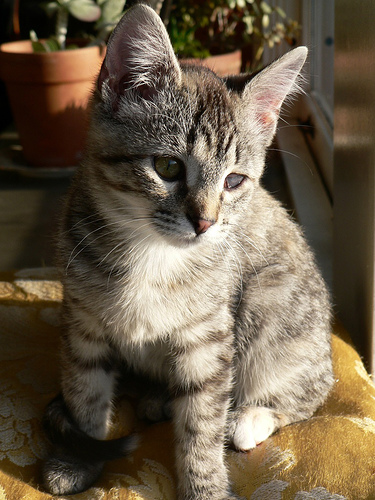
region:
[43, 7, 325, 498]
a kitten sitting on a table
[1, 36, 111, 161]
a clay pot sitting on the table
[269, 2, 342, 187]
the window next to the plants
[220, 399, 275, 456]
the white paw of the kitty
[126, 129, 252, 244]
the sad looking kitty face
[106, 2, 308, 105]
the big ears of the kitty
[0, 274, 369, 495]
the blanket the kitty is sitting on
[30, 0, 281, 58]
the plants sitting in the pots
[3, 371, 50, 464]
the flower on the blanket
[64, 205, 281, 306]
the whiskers on the kitty's face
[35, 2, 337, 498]
the kitten on the cushion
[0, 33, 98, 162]
the potted plant behind the kitten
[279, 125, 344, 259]
the window sill behind the kitten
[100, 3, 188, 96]
the ear of the kitten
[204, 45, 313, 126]
the ear of the kitten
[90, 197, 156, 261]
the whiskers on the kitten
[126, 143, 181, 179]
the eye of the kitten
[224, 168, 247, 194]
the eye of the kitten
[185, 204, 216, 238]
the nose of the kitten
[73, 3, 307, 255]
the head of the kitten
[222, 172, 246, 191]
Cat's left eye is milky colored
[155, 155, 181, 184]
Cat has dark right eye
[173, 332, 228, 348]
Cat's fur has grey stripes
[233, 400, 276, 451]
Cat's back paw is white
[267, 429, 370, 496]
soft yellow seating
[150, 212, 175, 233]
Cat's mouth has black dots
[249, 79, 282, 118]
Cat's left ear is pink inside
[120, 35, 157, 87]
Cat has fur in ears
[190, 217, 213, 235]
pink and black nose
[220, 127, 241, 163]
a triangle on cat's head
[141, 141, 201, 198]
a green eye on face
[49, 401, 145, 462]
a tail curled around a leg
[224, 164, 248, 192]
an eye socket on cat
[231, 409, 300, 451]
a white paw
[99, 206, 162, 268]
long white whiskers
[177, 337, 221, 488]
black stripe on gray fur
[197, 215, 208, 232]
a tiny pink nose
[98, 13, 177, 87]
a hairy pointy ear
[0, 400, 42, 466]
a white flower on gold brocade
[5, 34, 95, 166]
a potted plant behind the cat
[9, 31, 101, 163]
flower pot behind the kitten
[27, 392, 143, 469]
tail curled around the kitten's leg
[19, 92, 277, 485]
kitten sitting on a yellow cushion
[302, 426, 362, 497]
yellow and white cushion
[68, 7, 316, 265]
kitten looking away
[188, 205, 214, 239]
tiny kitten nose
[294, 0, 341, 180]
window behind the kitten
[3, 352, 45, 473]
white flowers on the yellow pillow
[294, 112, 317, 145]
handle on the window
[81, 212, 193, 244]
kitten whiskers